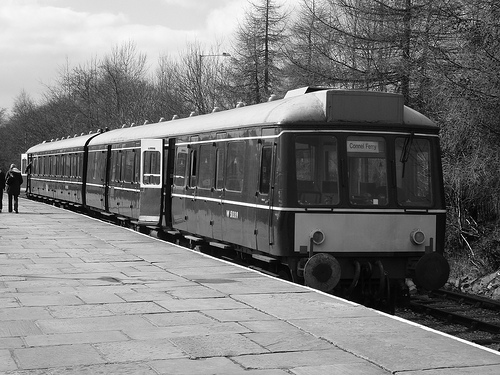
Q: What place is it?
A: It is a sidewalk.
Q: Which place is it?
A: It is a sidewalk.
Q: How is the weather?
A: It is cloudy.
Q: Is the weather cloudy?
A: Yes, it is cloudy.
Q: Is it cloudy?
A: Yes, it is cloudy.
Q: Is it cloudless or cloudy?
A: It is cloudy.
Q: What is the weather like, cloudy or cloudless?
A: It is cloudy.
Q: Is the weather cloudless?
A: No, it is cloudy.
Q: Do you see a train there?
A: Yes, there is a train.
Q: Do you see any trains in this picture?
A: Yes, there is a train.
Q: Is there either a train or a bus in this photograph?
A: Yes, there is a train.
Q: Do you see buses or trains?
A: Yes, there is a train.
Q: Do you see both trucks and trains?
A: No, there is a train but no trucks.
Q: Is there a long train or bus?
A: Yes, there is a long train.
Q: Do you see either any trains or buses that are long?
A: Yes, the train is long.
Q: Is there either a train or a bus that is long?
A: Yes, the train is long.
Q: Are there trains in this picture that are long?
A: Yes, there is a long train.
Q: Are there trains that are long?
A: Yes, there is a train that is long.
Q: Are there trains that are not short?
A: Yes, there is a long train.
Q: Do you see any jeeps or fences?
A: No, there are no fences or jeeps.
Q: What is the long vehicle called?
A: The vehicle is a train.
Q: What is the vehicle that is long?
A: The vehicle is a train.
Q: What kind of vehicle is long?
A: The vehicle is a train.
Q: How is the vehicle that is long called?
A: The vehicle is a train.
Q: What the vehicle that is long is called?
A: The vehicle is a train.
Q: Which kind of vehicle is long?
A: The vehicle is a train.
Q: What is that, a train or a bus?
A: That is a train.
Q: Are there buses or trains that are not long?
A: No, there is a train but it is long.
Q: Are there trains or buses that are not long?
A: No, there is a train but it is long.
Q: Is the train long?
A: Yes, the train is long.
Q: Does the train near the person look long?
A: Yes, the train is long.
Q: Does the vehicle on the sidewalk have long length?
A: Yes, the train is long.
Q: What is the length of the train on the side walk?
A: The train is long.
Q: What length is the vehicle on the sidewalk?
A: The train is long.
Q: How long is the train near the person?
A: The train is long.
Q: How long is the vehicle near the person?
A: The train is long.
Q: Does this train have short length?
A: No, the train is long.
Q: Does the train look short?
A: No, the train is long.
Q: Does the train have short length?
A: No, the train is long.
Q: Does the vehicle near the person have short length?
A: No, the train is long.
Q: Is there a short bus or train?
A: No, there is a train but it is long.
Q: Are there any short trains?
A: No, there is a train but it is long.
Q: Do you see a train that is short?
A: No, there is a train but it is long.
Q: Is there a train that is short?
A: No, there is a train but it is long.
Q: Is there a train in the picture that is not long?
A: No, there is a train but it is long.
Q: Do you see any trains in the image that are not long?
A: No, there is a train but it is long.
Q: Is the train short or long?
A: The train is long.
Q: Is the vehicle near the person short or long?
A: The train is long.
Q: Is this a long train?
A: Yes, this is a long train.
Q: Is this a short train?
A: No, this is a long train.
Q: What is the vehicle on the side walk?
A: The vehicle is a train.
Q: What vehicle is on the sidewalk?
A: The vehicle is a train.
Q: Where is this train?
A: The train is on the sidewalk.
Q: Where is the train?
A: The train is on the sidewalk.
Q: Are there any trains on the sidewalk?
A: Yes, there is a train on the sidewalk.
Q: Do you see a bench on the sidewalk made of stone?
A: No, there is a train on the side walk.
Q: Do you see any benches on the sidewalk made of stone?
A: No, there is a train on the side walk.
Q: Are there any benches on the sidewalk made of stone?
A: No, there is a train on the side walk.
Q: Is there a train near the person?
A: Yes, there is a train near the person.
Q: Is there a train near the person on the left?
A: Yes, there is a train near the person.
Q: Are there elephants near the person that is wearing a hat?
A: No, there is a train near the person.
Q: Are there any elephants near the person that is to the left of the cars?
A: No, there is a train near the person.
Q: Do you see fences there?
A: No, there are no fences.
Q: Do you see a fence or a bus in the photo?
A: No, there are no fences or buses.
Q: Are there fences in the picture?
A: No, there are no fences.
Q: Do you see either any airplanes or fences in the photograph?
A: No, there are no fences or airplanes.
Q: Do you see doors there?
A: Yes, there is a door.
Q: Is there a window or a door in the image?
A: Yes, there is a door.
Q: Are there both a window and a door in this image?
A: Yes, there are both a door and a window.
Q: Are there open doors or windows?
A: Yes, there is an open door.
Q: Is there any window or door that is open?
A: Yes, the door is open.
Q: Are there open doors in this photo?
A: Yes, there is an open door.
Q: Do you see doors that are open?
A: Yes, there is a door that is open.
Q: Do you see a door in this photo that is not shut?
A: Yes, there is a open door.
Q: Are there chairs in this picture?
A: No, there are no chairs.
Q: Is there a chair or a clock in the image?
A: No, there are no chairs or clocks.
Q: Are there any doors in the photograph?
A: Yes, there is a door.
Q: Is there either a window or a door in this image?
A: Yes, there is a door.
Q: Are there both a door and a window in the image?
A: Yes, there are both a door and a window.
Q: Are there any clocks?
A: No, there are no clocks.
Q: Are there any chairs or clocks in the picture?
A: No, there are no clocks or chairs.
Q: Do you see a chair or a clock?
A: No, there are no clocks or chairs.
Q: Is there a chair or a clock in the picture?
A: No, there are no clocks or chairs.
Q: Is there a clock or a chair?
A: No, there are no clocks or chairs.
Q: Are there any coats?
A: Yes, there is a coat.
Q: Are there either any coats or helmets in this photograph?
A: Yes, there is a coat.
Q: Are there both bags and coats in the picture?
A: No, there is a coat but no bags.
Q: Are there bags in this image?
A: No, there are no bags.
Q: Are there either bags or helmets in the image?
A: No, there are no bags or helmets.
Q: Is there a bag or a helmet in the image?
A: No, there are no bags or helmets.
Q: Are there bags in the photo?
A: No, there are no bags.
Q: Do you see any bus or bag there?
A: No, there are no bags or buses.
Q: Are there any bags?
A: No, there are no bags.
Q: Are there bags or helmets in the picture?
A: No, there are no bags or helmets.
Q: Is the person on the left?
A: Yes, the person is on the left of the image.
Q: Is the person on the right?
A: No, the person is on the left of the image.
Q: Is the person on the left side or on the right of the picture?
A: The person is on the left of the image.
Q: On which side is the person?
A: The person is on the left of the image.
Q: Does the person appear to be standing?
A: Yes, the person is standing.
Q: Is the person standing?
A: Yes, the person is standing.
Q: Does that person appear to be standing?
A: Yes, the person is standing.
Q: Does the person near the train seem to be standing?
A: Yes, the person is standing.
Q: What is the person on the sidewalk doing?
A: The person is standing.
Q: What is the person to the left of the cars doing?
A: The person is standing.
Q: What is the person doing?
A: The person is standing.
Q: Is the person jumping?
A: No, the person is standing.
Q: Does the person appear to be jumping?
A: No, the person is standing.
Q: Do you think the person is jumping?
A: No, the person is standing.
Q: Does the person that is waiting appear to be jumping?
A: No, the person is standing.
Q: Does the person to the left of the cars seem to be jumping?
A: No, the person is standing.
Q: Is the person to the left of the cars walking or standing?
A: The person is standing.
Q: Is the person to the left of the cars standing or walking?
A: The person is standing.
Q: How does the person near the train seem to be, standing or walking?
A: The person is standing.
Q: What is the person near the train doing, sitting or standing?
A: The person is standing.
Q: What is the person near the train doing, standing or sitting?
A: The person is standing.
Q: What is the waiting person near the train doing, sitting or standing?
A: The person is standing.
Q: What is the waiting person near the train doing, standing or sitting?
A: The person is standing.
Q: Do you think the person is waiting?
A: Yes, the person is waiting.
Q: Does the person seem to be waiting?
A: Yes, the person is waiting.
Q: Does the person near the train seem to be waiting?
A: Yes, the person is waiting.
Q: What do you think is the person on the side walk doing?
A: The person is waiting.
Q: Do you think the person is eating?
A: No, the person is waiting.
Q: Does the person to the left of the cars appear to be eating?
A: No, the person is waiting.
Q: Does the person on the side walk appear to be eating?
A: No, the person is waiting.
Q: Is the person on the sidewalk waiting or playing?
A: The person is waiting.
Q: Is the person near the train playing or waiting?
A: The person is waiting.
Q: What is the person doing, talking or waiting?
A: The person is waiting.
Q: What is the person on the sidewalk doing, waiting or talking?
A: The person is waiting.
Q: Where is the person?
A: The person is on the side walk.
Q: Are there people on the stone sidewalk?
A: Yes, there is a person on the sidewalk.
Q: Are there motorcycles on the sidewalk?
A: No, there is a person on the sidewalk.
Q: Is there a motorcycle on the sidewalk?
A: No, there is a person on the sidewalk.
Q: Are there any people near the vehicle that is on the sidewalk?
A: Yes, there is a person near the train.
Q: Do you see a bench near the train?
A: No, there is a person near the train.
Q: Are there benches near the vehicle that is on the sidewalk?
A: No, there is a person near the train.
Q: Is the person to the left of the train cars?
A: Yes, the person is to the left of the cars.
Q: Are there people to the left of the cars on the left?
A: Yes, there is a person to the left of the cars.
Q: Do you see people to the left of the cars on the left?
A: Yes, there is a person to the left of the cars.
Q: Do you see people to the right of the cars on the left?
A: No, the person is to the left of the cars.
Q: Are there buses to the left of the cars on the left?
A: No, there is a person to the left of the cars.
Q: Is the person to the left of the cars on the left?
A: Yes, the person is to the left of the cars.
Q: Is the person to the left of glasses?
A: No, the person is to the left of the cars.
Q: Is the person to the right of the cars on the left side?
A: No, the person is to the left of the cars.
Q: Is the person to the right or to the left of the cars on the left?
A: The person is to the left of the cars.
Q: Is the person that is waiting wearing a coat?
A: Yes, the person is wearing a coat.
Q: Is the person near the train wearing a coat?
A: Yes, the person is wearing a coat.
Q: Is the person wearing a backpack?
A: No, the person is wearing a coat.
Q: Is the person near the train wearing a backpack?
A: No, the person is wearing a coat.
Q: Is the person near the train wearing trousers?
A: Yes, the person is wearing trousers.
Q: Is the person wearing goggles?
A: No, the person is wearing trousers.